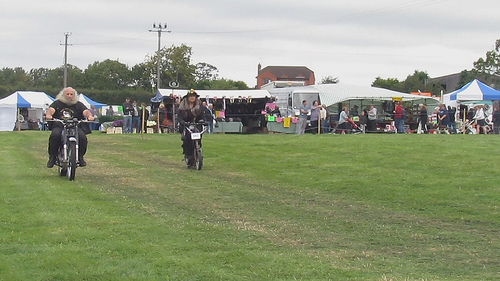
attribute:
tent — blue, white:
[432, 60, 497, 120]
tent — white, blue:
[1, 63, 113, 154]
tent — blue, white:
[0, 88, 53, 129]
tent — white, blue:
[439, 75, 499, 106]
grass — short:
[2, 130, 499, 279]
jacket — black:
[175, 88, 205, 135]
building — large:
[253, 60, 315, 92]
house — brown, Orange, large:
[243, 57, 320, 103]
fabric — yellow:
[275, 113, 303, 128]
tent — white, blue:
[0, 89, 57, 109]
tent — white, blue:
[75, 88, 107, 108]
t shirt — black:
[51, 100, 86, 126]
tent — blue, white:
[449, 77, 496, 109]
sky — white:
[1, 2, 499, 86]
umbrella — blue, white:
[444, 75, 498, 106]